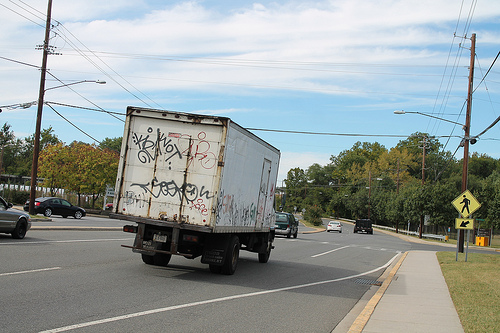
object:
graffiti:
[126, 127, 211, 217]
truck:
[107, 103, 281, 276]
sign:
[453, 218, 476, 231]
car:
[326, 219, 342, 233]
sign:
[450, 189, 483, 219]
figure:
[458, 194, 473, 215]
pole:
[460, 33, 474, 187]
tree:
[37, 141, 113, 209]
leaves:
[34, 139, 114, 196]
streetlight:
[389, 109, 405, 115]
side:
[214, 127, 279, 228]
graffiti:
[221, 196, 280, 225]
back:
[109, 106, 220, 227]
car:
[22, 196, 88, 218]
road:
[0, 216, 497, 332]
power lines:
[243, 130, 459, 139]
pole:
[30, 0, 53, 216]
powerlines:
[44, 70, 466, 99]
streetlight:
[84, 78, 106, 84]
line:
[310, 239, 347, 265]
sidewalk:
[333, 250, 459, 333]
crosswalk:
[0, 214, 401, 332]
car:
[350, 219, 373, 236]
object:
[473, 236, 489, 246]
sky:
[0, 0, 499, 195]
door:
[252, 157, 274, 230]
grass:
[438, 250, 499, 332]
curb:
[348, 250, 409, 333]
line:
[25, 242, 403, 332]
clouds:
[0, 0, 499, 129]